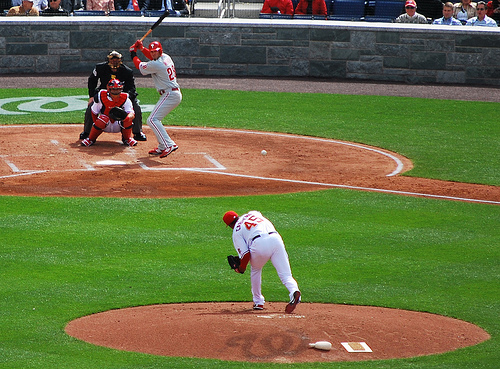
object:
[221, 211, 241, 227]
hat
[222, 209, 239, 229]
head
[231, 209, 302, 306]
uniform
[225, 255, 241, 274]
hand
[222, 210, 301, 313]
pitcher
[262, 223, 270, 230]
white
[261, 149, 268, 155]
baseball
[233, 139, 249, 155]
air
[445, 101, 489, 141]
grass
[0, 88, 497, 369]
field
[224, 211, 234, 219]
red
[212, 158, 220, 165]
white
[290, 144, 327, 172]
dirt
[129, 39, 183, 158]
player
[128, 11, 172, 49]
bat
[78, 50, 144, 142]
umpire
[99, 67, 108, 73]
black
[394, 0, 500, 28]
spectators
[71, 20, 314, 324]
game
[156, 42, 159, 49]
red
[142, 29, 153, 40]
brown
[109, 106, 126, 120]
mitt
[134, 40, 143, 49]
hand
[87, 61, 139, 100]
clothes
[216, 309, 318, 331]
mound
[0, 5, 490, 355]
photo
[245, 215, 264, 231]
45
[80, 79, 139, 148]
catcher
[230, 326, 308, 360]
w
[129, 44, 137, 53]
handed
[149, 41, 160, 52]
hat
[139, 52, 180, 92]
shirt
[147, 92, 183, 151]
pants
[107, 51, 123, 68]
mask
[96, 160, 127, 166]
home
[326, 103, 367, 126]
green